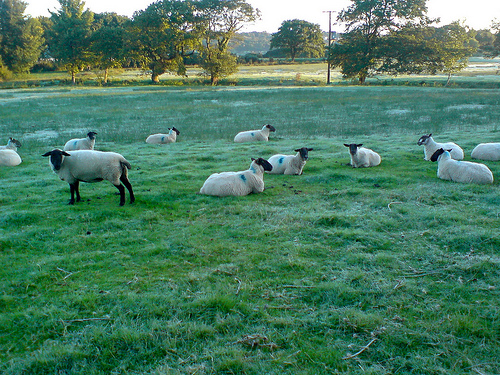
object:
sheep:
[431, 148, 494, 185]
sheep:
[42, 149, 135, 206]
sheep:
[200, 158, 274, 196]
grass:
[2, 87, 496, 374]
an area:
[4, 87, 496, 373]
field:
[0, 49, 493, 373]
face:
[49, 151, 63, 171]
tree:
[41, 1, 103, 84]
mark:
[240, 174, 247, 182]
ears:
[440, 148, 444, 152]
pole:
[327, 11, 332, 85]